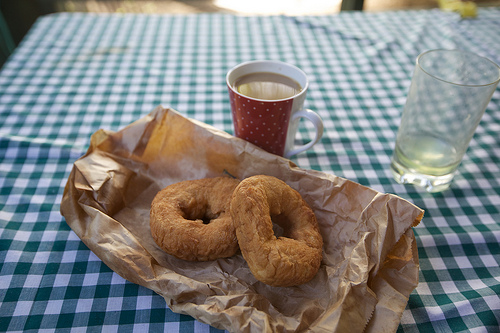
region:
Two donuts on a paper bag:
[131, 164, 347, 290]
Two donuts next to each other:
[127, 160, 352, 290]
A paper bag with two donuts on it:
[46, 102, 414, 330]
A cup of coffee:
[217, 52, 349, 162]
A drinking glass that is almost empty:
[360, 32, 499, 207]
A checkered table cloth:
[35, 19, 286, 145]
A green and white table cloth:
[32, 22, 329, 293]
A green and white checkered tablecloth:
[12, 17, 115, 326]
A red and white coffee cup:
[215, 41, 337, 173]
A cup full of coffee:
[211, 51, 338, 173]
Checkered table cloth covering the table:
[12, 5, 497, 326]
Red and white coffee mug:
[201, 47, 344, 167]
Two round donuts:
[100, 160, 348, 282]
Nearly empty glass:
[382, 18, 483, 199]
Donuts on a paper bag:
[97, 148, 374, 295]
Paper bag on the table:
[47, 76, 458, 330]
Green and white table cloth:
[5, 2, 490, 325]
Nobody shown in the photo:
[21, 4, 487, 325]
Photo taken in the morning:
[14, 6, 496, 326]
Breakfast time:
[77, 35, 490, 323]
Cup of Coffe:
[231, 50, 324, 150]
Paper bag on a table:
[59, 99, 432, 306]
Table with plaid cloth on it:
[55, 22, 215, 91]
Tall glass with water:
[409, 32, 465, 207]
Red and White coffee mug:
[236, 51, 313, 158]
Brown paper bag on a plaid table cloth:
[71, 111, 433, 316]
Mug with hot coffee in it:
[223, 66, 308, 145]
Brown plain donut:
[165, 172, 241, 251]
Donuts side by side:
[157, 155, 317, 278]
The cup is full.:
[214, 52, 329, 174]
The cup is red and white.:
[213, 53, 326, 181]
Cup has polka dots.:
[217, 52, 324, 176]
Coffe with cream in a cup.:
[208, 52, 332, 168]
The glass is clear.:
[379, 40, 497, 199]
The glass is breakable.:
[381, 35, 498, 202]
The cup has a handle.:
[202, 55, 329, 175]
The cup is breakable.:
[221, 47, 331, 167]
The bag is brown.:
[34, 101, 425, 331]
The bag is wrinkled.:
[44, 92, 431, 331]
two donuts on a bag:
[136, 154, 341, 296]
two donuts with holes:
[140, 157, 330, 299]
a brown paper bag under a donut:
[53, 101, 435, 328]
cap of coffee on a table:
[214, 54, 330, 165]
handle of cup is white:
[289, 105, 330, 157]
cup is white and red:
[216, 50, 327, 167]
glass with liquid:
[382, 37, 498, 202]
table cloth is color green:
[2, 6, 498, 331]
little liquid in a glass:
[382, 130, 470, 200]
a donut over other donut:
[219, 159, 341, 296]